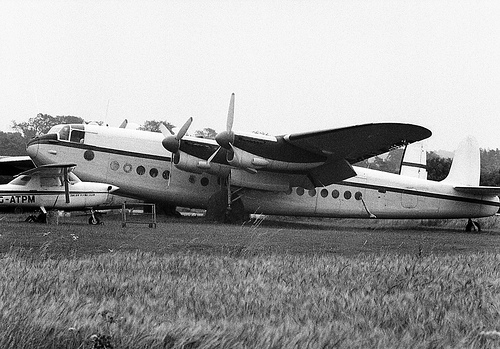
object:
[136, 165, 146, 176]
circle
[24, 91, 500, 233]
plane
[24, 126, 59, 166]
nose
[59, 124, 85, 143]
cockpit window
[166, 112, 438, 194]
sidewing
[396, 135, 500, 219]
tail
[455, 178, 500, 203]
tailwing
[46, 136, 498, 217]
stripe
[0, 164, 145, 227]
plane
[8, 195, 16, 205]
letter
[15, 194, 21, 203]
letter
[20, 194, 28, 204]
letter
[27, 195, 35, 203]
letter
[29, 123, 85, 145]
cockpit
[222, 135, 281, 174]
motor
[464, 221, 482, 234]
wheel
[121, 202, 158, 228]
cart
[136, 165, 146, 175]
window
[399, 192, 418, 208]
door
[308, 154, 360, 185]
wingflap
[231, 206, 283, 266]
grass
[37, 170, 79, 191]
cockpit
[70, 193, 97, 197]
numbers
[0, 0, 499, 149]
sky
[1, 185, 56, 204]
sidewing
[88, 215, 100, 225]
wheel